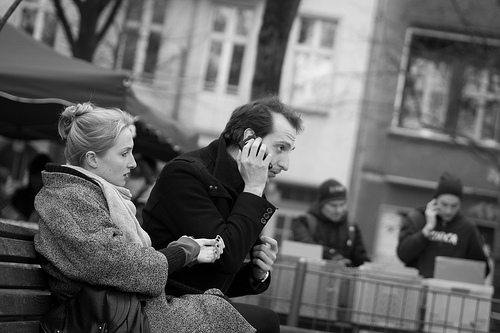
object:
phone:
[238, 135, 273, 170]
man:
[139, 95, 302, 332]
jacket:
[139, 136, 276, 306]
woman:
[29, 101, 261, 333]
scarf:
[60, 164, 153, 252]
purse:
[38, 281, 153, 333]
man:
[395, 206, 490, 286]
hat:
[434, 170, 463, 201]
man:
[289, 180, 369, 269]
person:
[0, 155, 59, 220]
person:
[123, 144, 161, 229]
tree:
[310, 1, 499, 189]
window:
[288, 13, 341, 118]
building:
[0, 1, 500, 292]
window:
[200, 1, 258, 97]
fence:
[228, 258, 500, 333]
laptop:
[434, 256, 485, 285]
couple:
[31, 101, 300, 333]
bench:
[0, 222, 49, 333]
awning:
[0, 22, 198, 163]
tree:
[252, 0, 299, 108]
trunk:
[53, 1, 121, 62]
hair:
[220, 96, 304, 147]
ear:
[244, 128, 256, 139]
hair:
[58, 102, 131, 167]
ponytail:
[58, 101, 96, 134]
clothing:
[31, 164, 257, 333]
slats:
[1, 219, 53, 332]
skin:
[277, 124, 297, 140]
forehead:
[281, 128, 299, 146]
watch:
[255, 271, 270, 289]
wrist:
[251, 269, 267, 283]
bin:
[349, 261, 417, 333]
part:
[317, 265, 363, 330]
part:
[403, 235, 426, 257]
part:
[61, 226, 99, 274]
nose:
[277, 155, 288, 171]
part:
[161, 182, 207, 230]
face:
[102, 137, 137, 187]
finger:
[260, 236, 279, 253]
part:
[260, 233, 270, 245]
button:
[266, 208, 272, 214]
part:
[277, 216, 285, 229]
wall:
[345, 0, 500, 333]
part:
[374, 146, 412, 162]